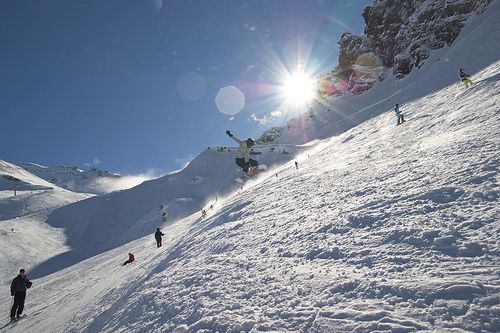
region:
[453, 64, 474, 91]
a person wearing yellow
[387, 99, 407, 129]
a person wearing blue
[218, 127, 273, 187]
a person jumping on a snowboard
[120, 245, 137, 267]
a person in a red jacket sitting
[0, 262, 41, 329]
a person on a snowboard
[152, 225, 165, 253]
a person standing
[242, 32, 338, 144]
the sun with flares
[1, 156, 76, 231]
a snow covered hill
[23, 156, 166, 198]
a snow covered hill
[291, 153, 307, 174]
a person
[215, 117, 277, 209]
The person is snowboarding.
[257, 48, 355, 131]
The sun is shining.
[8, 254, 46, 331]
The person is in dark clothing.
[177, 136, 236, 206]
There is a hill in the snow.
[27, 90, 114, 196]
The sky is blue.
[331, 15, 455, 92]
There are trees covered in snow.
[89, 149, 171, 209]
There are clouds in the sky.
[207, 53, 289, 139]
The sun is producing a glare in the picture.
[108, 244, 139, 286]
There is a person sitting on the snow.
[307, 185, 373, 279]
The snow has tracks.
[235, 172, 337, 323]
the snow is white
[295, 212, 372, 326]
the snow is white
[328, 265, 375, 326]
the snow is white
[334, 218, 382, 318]
the snow is white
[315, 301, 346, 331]
the snow is white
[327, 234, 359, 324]
the snow is white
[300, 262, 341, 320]
the snow is white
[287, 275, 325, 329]
the snow is white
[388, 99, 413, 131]
skier on snow slope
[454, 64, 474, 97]
skier on snow slope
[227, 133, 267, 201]
skier on snow slope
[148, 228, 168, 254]
skier on snow slope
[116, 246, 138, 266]
skier on snow slope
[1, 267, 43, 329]
skier on snow slope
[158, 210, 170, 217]
skier on snow slope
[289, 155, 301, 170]
skier on snow slope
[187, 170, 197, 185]
skier on snow slope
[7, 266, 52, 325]
person standing on the snow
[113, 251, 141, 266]
person sitting on the snow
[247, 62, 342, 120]
sun shining brightly in the sky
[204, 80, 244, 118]
glint of the sun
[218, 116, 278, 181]
person in the air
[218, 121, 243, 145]
arm rasied up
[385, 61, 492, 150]
two people in the snow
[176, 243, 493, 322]
the snow is not smooth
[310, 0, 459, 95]
trees covered in snow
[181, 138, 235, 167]
hilltop covered in snow